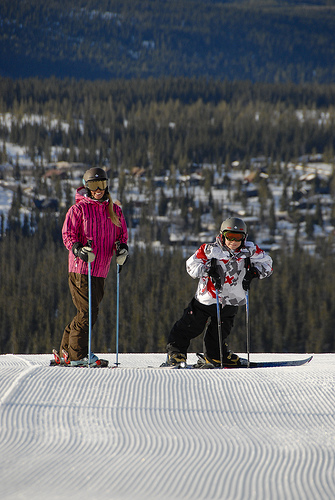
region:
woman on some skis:
[46, 159, 136, 376]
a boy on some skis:
[159, 211, 315, 374]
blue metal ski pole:
[76, 240, 96, 370]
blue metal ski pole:
[109, 239, 125, 369]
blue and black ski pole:
[207, 262, 227, 371]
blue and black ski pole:
[241, 256, 252, 374]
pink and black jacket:
[61, 184, 131, 276]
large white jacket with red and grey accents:
[182, 232, 274, 305]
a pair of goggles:
[221, 230, 249, 242]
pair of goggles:
[85, 175, 112, 192]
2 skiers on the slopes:
[16, 152, 266, 356]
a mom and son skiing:
[48, 165, 298, 427]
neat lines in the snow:
[23, 337, 310, 479]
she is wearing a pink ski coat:
[50, 165, 145, 380]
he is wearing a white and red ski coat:
[168, 214, 304, 385]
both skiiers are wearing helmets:
[72, 157, 282, 266]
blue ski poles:
[73, 246, 146, 379]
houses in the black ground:
[14, 107, 326, 277]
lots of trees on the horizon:
[12, 69, 319, 171]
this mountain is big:
[5, 4, 292, 226]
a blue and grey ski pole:
[83, 246, 100, 369]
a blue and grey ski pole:
[112, 235, 123, 366]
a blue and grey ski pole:
[211, 257, 227, 368]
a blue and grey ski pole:
[242, 251, 252, 366]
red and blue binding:
[53, 348, 64, 366]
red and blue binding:
[61, 349, 104, 367]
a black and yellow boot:
[170, 347, 187, 368]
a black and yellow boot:
[201, 347, 244, 367]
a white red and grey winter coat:
[186, 243, 274, 310]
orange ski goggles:
[218, 227, 247, 241]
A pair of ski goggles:
[217, 227, 247, 244]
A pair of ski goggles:
[83, 177, 112, 197]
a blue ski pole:
[83, 248, 97, 376]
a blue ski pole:
[112, 247, 126, 368]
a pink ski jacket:
[53, 185, 133, 281]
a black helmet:
[79, 164, 113, 185]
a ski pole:
[211, 263, 235, 369]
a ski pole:
[240, 261, 258, 374]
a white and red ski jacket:
[183, 241, 271, 305]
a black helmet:
[219, 214, 249, 237]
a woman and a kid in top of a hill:
[52, 158, 278, 385]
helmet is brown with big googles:
[73, 165, 115, 209]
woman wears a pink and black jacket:
[55, 163, 136, 285]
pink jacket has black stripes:
[51, 188, 132, 275]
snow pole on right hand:
[105, 245, 131, 362]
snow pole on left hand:
[75, 243, 105, 362]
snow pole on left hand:
[201, 258, 229, 368]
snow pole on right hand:
[232, 259, 254, 366]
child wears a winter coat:
[167, 208, 282, 397]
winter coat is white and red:
[180, 242, 275, 311]